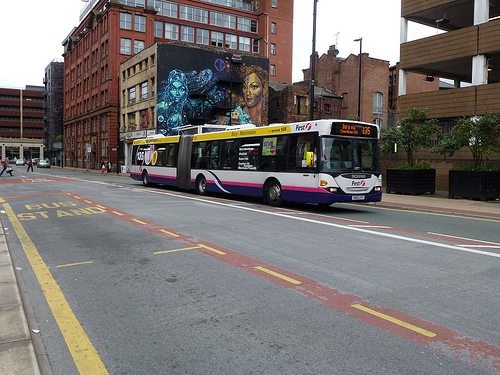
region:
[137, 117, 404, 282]
a bus is on the highway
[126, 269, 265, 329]
the road is made of asphalt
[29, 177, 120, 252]
floor has yellow lanes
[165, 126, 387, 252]
the bus is twice long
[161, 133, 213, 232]
the door is closed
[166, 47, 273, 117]
the posters are beside the raod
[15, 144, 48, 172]
peopl are crosing the road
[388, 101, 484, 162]
plants are on the wall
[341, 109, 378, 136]
the words are written in orange color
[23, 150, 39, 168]
the blouse is red in color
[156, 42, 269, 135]
Painted women on side of building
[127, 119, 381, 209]
Long bus on road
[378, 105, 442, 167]
Tree by parking ramp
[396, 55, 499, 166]
Brown parking ramp by trees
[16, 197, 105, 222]
Yellow words that say Bus Stand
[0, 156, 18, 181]
Person walking across road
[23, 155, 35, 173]
Person walking across road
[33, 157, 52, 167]
Car driving on road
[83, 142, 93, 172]
Sign on side of street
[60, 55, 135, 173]
Red brick building by road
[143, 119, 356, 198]
white and blue bus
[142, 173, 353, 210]
pink stripe on bus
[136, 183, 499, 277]
white line on road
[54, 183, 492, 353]
yellow lines on road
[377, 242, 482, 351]
road is dark grey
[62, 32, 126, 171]
tall red brick building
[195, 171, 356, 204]
black wheels on bus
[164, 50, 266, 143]
large mural on building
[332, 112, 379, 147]
orange destination on bus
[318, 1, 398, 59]
white and cloudy sky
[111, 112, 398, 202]
a double bus on a street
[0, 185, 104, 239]
yellow words painted on a the street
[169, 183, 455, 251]
white lines painted on the street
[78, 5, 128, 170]
a tall red brick building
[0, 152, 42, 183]
people crossing a street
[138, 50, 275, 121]
a painting on the side of a building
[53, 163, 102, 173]
a concrete sidewalk in front of a building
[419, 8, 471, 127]
a parking garage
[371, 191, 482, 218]
a concrete sidewalk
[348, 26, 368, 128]
a tall street light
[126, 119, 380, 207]
the long bus along the curb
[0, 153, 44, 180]
the people crossing the street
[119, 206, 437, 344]
the traffic lines on the road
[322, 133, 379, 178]
the windshield of the bus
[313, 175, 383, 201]
the lights on the front of the bus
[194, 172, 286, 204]
the tires on the truck.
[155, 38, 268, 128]
the apinting on the wall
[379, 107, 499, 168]
the trees in the planters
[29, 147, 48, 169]
the cars parked on the curbside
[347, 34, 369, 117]
the black streetlight on the corner